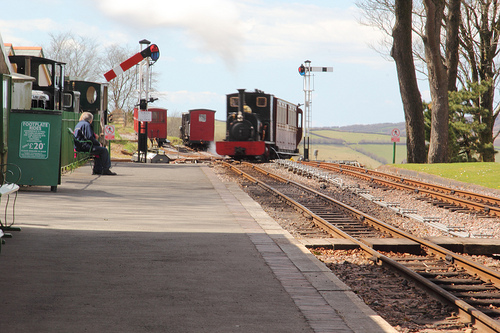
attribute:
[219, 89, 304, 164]
train — coming this way, black, red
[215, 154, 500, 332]
tracks — rusted steel, rusty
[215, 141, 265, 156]
bumper — red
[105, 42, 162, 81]
train sign — red, white, here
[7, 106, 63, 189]
trash can — solid green, outdoors, lined, metal, green, here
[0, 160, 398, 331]
platform — concrete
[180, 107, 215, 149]
train — heading away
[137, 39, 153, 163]
pole — metal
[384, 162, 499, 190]
field — grassy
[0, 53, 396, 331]
train station — here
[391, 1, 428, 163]
tree — old, strong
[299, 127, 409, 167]
hill — green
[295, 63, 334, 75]
train sign — here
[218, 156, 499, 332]
gravel — stone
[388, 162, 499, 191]
grass — short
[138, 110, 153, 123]
sign — white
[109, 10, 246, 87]
smoke — rising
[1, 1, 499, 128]
sky — sunny, cloudy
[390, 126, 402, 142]
sign — red, white